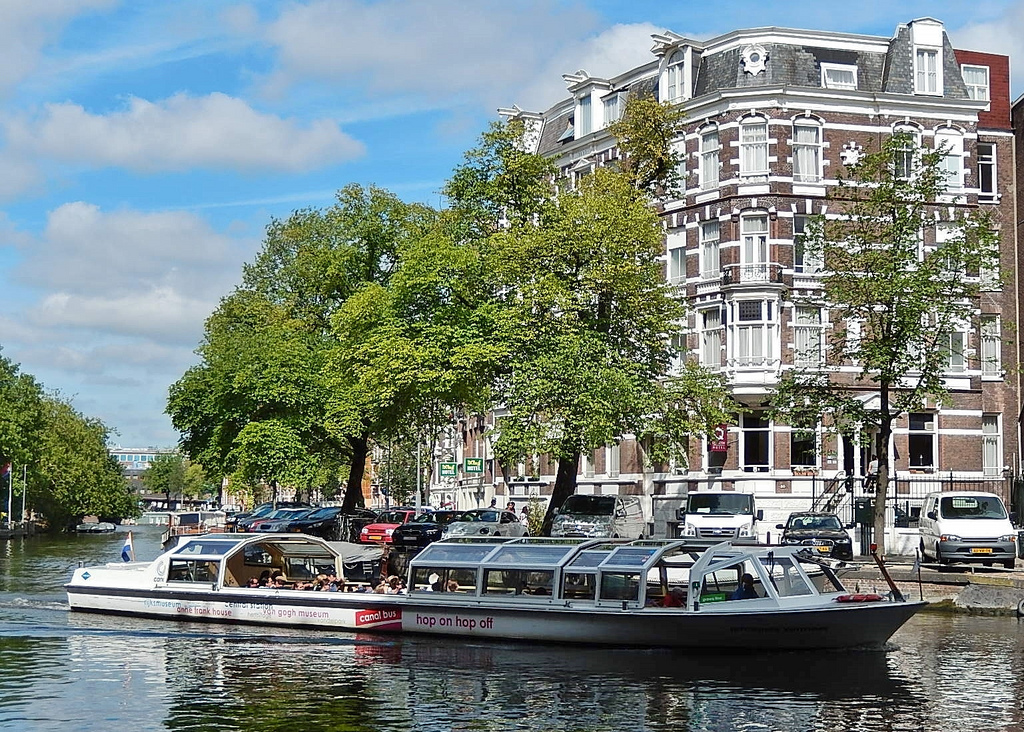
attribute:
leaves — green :
[466, 375, 489, 394]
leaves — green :
[434, 276, 529, 356]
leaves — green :
[361, 298, 428, 372]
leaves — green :
[310, 336, 383, 429]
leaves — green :
[253, 333, 280, 376]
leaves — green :
[175, 388, 253, 466]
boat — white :
[48, 431, 971, 730]